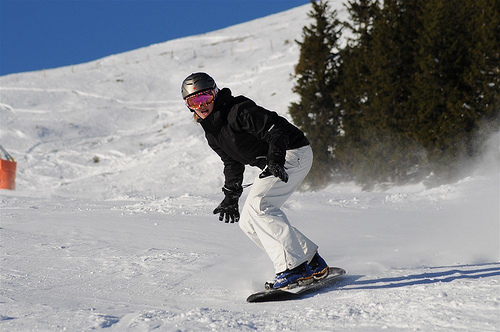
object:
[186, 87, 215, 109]
goggles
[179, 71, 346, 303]
skier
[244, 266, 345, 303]
snowboard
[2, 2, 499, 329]
snow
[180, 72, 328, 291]
lady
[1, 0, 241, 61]
sky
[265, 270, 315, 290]
feet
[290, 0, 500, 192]
bush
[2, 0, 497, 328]
slope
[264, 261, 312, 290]
boot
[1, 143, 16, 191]
orange bucket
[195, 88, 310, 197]
jacket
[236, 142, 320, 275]
pants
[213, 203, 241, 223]
hand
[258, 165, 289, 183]
hand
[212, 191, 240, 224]
glove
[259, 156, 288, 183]
glove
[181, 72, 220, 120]
head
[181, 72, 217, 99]
helmet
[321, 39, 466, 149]
green leaves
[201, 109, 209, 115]
mouth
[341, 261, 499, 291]
shadow